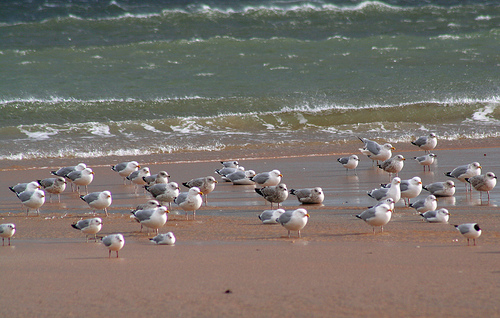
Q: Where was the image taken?
A: It was taken at the beach.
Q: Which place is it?
A: It is a beach.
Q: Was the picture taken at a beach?
A: Yes, it was taken in a beach.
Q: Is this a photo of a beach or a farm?
A: It is showing a beach.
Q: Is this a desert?
A: No, it is a beach.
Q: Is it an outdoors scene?
A: Yes, it is outdoors.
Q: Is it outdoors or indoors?
A: It is outdoors.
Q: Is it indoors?
A: No, it is outdoors.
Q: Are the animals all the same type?
A: No, there are both seagulls and birds.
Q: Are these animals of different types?
A: Yes, they are seagulls and birds.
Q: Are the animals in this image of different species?
A: Yes, they are seagulls and birds.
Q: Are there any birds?
A: Yes, there is a bird.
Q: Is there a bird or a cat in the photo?
A: Yes, there is a bird.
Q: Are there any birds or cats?
A: Yes, there is a bird.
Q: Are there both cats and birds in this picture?
A: No, there is a bird but no cats.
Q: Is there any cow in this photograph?
A: No, there are no cows.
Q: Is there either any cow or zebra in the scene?
A: No, there are no cows or zebras.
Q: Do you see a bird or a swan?
A: Yes, there is a bird.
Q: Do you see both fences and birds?
A: No, there is a bird but no fences.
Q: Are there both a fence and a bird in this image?
A: No, there is a bird but no fences.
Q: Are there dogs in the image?
A: No, there are no dogs.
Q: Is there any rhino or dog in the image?
A: No, there are no dogs or rhinos.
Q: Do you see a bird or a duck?
A: Yes, there is a bird.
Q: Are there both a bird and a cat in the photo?
A: No, there is a bird but no cats.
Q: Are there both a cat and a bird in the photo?
A: No, there is a bird but no cats.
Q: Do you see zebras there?
A: No, there are no zebras.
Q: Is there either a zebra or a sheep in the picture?
A: No, there are no zebras or sheep.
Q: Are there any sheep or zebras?
A: No, there are no zebras or sheep.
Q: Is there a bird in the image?
A: Yes, there is a bird.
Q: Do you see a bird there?
A: Yes, there is a bird.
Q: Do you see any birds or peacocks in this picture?
A: Yes, there is a bird.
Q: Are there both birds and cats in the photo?
A: No, there is a bird but no cats.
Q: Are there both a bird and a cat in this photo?
A: No, there is a bird but no cats.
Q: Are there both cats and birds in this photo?
A: No, there is a bird but no cats.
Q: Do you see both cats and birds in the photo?
A: No, there is a bird but no cats.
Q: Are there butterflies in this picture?
A: No, there are no butterflies.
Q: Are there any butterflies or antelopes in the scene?
A: No, there are no butterflies or antelopes.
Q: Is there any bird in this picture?
A: Yes, there is a bird.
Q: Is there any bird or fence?
A: Yes, there is a bird.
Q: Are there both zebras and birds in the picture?
A: No, there is a bird but no zebras.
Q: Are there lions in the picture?
A: No, there are no lions.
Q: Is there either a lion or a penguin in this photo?
A: No, there are no lions or penguins.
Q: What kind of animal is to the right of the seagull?
A: The animal is a bird.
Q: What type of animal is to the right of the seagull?
A: The animal is a bird.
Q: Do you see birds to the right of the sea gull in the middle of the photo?
A: Yes, there is a bird to the right of the seagull.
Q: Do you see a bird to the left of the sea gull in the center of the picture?
A: No, the bird is to the right of the seagull.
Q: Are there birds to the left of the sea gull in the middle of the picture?
A: No, the bird is to the right of the seagull.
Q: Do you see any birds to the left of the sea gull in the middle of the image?
A: No, the bird is to the right of the seagull.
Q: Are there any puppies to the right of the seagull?
A: No, there is a bird to the right of the seagull.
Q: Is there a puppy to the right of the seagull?
A: No, there is a bird to the right of the seagull.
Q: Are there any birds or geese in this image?
A: Yes, there is a bird.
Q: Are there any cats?
A: No, there are no cats.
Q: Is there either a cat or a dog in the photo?
A: No, there are no cats or dogs.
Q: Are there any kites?
A: No, there are no kites.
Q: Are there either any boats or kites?
A: No, there are no kites or boats.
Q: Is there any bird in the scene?
A: Yes, there is a bird.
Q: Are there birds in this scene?
A: Yes, there is a bird.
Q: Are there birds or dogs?
A: Yes, there is a bird.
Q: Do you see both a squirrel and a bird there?
A: No, there is a bird but no squirrels.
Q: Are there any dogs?
A: No, there are no dogs.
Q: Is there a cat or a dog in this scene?
A: No, there are no dogs or cats.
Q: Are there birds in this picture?
A: Yes, there is a bird.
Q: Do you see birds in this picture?
A: Yes, there is a bird.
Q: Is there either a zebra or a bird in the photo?
A: Yes, there is a bird.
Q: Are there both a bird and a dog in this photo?
A: No, there is a bird but no dogs.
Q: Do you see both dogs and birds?
A: No, there is a bird but no dogs.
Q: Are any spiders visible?
A: No, there are no spiders.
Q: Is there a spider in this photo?
A: No, there are no spiders.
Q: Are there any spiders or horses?
A: No, there are no spiders or horses.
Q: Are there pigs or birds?
A: Yes, there is a bird.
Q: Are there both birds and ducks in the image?
A: No, there is a bird but no ducks.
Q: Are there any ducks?
A: No, there are no ducks.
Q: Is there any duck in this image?
A: No, there are no ducks.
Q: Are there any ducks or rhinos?
A: No, there are no ducks or rhinos.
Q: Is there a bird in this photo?
A: Yes, there is a bird.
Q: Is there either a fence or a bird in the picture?
A: Yes, there is a bird.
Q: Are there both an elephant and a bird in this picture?
A: No, there is a bird but no elephants.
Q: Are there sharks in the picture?
A: No, there are no sharks.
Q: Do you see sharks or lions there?
A: No, there are no sharks or lions.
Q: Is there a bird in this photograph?
A: Yes, there is a bird.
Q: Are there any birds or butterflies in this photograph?
A: Yes, there is a bird.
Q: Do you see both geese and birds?
A: No, there is a bird but no geese.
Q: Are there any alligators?
A: No, there are no alligators.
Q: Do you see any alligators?
A: No, there are no alligators.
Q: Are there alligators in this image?
A: No, there are no alligators.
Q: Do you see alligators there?
A: No, there are no alligators.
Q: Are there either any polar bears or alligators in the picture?
A: No, there are no alligators or polar bears.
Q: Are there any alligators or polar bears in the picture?
A: No, there are no alligators or polar bears.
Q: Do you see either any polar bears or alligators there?
A: No, there are no alligators or polar bears.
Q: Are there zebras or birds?
A: Yes, there are birds.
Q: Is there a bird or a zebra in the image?
A: Yes, there are birds.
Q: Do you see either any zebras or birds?
A: Yes, there are birds.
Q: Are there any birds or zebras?
A: Yes, there are birds.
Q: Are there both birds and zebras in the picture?
A: No, there are birds but no zebras.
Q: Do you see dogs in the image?
A: No, there are no dogs.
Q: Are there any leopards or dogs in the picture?
A: No, there are no dogs or leopards.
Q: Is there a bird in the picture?
A: Yes, there are birds.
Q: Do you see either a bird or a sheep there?
A: Yes, there are birds.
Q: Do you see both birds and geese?
A: No, there are birds but no geese.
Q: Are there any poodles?
A: No, there are no poodles.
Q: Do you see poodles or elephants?
A: No, there are no poodles or elephants.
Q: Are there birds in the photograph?
A: Yes, there are birds.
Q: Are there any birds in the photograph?
A: Yes, there are birds.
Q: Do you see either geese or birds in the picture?
A: Yes, there are birds.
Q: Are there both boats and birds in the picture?
A: No, there are birds but no boats.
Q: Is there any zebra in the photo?
A: No, there are no zebras.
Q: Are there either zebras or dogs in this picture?
A: No, there are no zebras or dogs.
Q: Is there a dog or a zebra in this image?
A: No, there are no zebras or dogs.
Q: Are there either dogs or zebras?
A: No, there are no zebras or dogs.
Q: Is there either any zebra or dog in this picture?
A: No, there are no zebras or dogs.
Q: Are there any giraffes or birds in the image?
A: Yes, there is a bird.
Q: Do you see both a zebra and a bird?
A: No, there is a bird but no zebras.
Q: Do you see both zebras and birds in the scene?
A: No, there is a bird but no zebras.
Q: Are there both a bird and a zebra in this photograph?
A: No, there is a bird but no zebras.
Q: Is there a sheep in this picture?
A: No, there is no sheep.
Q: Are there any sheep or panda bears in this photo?
A: No, there are no sheep or panda bears.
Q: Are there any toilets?
A: No, there are no toilets.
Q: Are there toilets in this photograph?
A: No, there are no toilets.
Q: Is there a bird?
A: Yes, there are birds.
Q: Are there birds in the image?
A: Yes, there are birds.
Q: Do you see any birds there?
A: Yes, there are birds.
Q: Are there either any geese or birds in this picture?
A: Yes, there are birds.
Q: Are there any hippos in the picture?
A: No, there are no hippos.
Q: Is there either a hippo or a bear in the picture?
A: No, there are no hippos or bears.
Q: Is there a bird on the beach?
A: Yes, there are birds on the beach.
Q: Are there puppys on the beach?
A: No, there are birds on the beach.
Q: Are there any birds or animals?
A: Yes, there are birds.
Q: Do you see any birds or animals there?
A: Yes, there are birds.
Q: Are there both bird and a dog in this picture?
A: No, there are birds but no dogs.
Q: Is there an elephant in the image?
A: No, there are no elephants.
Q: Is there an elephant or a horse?
A: No, there are no elephants or horses.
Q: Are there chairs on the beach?
A: No, there are birds on the beach.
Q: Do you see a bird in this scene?
A: Yes, there are birds.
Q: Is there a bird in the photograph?
A: Yes, there are birds.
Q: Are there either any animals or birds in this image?
A: Yes, there are birds.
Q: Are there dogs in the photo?
A: No, there are no dogs.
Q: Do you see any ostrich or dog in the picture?
A: No, there are no dogs or ostriches.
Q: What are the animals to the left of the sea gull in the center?
A: The animals are birds.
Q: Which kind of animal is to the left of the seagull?
A: The animals are birds.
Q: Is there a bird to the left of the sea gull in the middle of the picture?
A: Yes, there are birds to the left of the seagull.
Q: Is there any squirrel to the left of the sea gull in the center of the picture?
A: No, there are birds to the left of the seagull.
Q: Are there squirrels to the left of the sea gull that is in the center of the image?
A: No, there are birds to the left of the seagull.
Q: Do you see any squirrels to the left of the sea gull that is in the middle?
A: No, there are birds to the left of the seagull.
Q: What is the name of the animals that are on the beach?
A: The animals are birds.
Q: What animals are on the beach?
A: The animals are birds.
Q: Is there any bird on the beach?
A: Yes, there are birds on the beach.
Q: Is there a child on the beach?
A: No, there are birds on the beach.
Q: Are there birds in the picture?
A: Yes, there are birds.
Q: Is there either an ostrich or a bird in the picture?
A: Yes, there are birds.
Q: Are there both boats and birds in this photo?
A: No, there are birds but no boats.